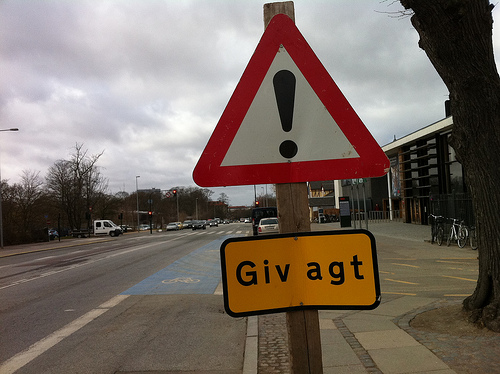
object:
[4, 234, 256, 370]
road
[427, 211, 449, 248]
bike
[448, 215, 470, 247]
bike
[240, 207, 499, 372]
sidewalk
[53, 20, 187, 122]
clouds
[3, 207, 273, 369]
land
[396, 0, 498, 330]
tree trunk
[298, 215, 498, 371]
sidewalk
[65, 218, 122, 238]
truck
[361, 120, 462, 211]
building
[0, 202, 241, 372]
road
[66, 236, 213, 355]
street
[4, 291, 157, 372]
line